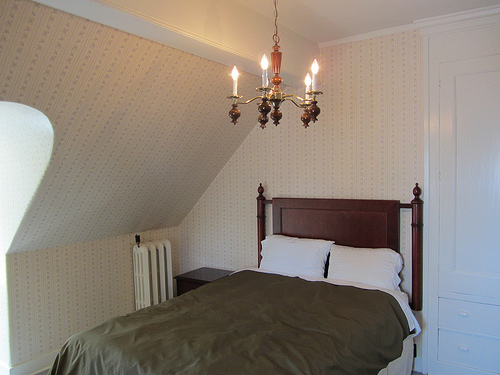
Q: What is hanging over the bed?
A: A chandelier.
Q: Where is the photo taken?
A: A bedroom.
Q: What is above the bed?
A: A brown headboard.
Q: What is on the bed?
A: Two white pillows.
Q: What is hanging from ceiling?
A: Chandelier.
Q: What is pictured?
A: A bedroom.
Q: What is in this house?
A: A bedroom.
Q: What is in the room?
A: A bed.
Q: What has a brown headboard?
A: A bed.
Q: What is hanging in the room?
A: A light.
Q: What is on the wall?
A: White wallpaper.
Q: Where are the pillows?
A: On the bed.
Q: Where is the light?
A: Hanging from the ceiling.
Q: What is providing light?
A: The chandelier.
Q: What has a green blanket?
A: The bed.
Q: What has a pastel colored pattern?
A: The wallpaper.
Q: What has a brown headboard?
A: The bed.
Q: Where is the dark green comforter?
A: On the bed.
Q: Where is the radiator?
A: Against the wall.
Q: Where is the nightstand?
A: Next to the bed.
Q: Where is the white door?
A: Next to the bed.